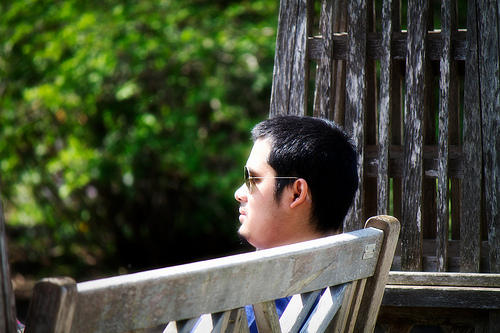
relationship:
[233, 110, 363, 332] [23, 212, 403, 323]
man sits on bench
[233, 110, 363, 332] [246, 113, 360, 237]
man has hair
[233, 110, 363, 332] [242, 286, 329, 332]
man has shirt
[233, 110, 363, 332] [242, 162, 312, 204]
man wears sunglasses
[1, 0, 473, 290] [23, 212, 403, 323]
trees near bench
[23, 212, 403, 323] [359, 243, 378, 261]
bench has marking tag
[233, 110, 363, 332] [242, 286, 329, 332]
man wears shirt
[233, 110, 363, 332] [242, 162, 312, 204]
man looks through sunglasses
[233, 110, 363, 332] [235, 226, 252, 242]
man has goattee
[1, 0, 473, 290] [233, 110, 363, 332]
trees near man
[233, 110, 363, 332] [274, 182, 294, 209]
man has sideburns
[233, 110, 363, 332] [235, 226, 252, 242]
man has a goattee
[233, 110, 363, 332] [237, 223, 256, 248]
man has a chin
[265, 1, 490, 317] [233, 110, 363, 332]
fence near man